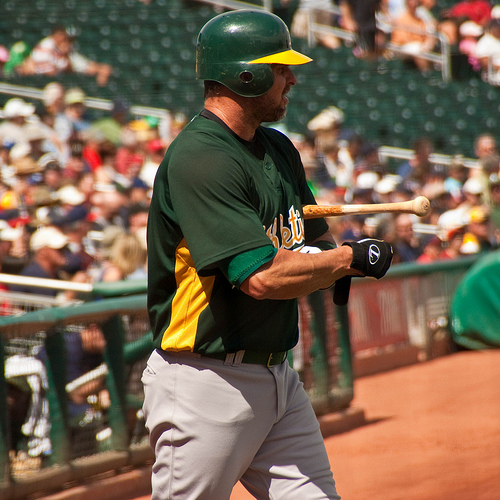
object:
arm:
[246, 246, 352, 300]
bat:
[304, 232, 337, 254]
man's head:
[195, 6, 312, 122]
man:
[391, 213, 420, 261]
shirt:
[393, 237, 423, 261]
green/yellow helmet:
[194, 8, 312, 99]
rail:
[214, 1, 458, 85]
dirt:
[401, 397, 490, 472]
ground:
[424, 385, 451, 425]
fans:
[0, 32, 145, 277]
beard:
[264, 109, 287, 123]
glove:
[341, 238, 393, 281]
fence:
[0, 275, 357, 497]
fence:
[348, 255, 491, 362]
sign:
[350, 280, 426, 354]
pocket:
[165, 378, 255, 429]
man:
[9, 225, 72, 295]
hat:
[28, 225, 72, 253]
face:
[241, 64, 298, 124]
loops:
[222, 349, 247, 369]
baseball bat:
[300, 196, 430, 220]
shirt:
[145, 107, 329, 358]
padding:
[45, 326, 88, 415]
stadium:
[0, 2, 497, 499]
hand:
[340, 237, 396, 277]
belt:
[203, 351, 288, 369]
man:
[139, 8, 392, 500]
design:
[368, 244, 381, 265]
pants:
[139, 349, 339, 499]